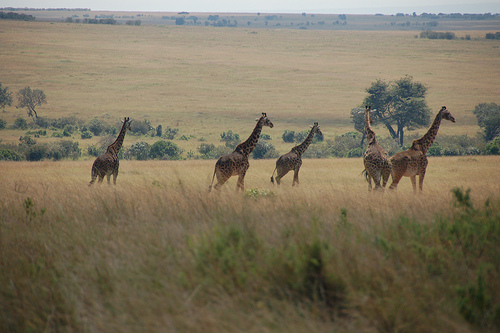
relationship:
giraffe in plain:
[91, 118, 135, 183] [1, 8, 498, 331]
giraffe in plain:
[214, 110, 273, 188] [1, 8, 498, 331]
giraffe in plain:
[271, 121, 323, 187] [1, 8, 498, 331]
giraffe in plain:
[363, 104, 393, 188] [1, 8, 498, 331]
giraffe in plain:
[389, 105, 455, 190] [1, 8, 498, 331]